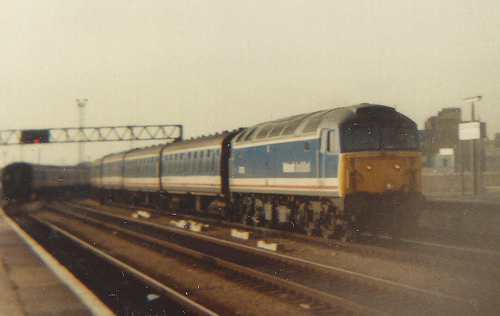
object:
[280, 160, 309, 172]
text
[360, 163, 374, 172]
headlights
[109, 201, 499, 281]
track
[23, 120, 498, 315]
dirt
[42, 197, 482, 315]
tracks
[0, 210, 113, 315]
platform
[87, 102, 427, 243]
train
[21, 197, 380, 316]
train tracks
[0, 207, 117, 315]
line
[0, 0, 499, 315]
picture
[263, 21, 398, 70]
air